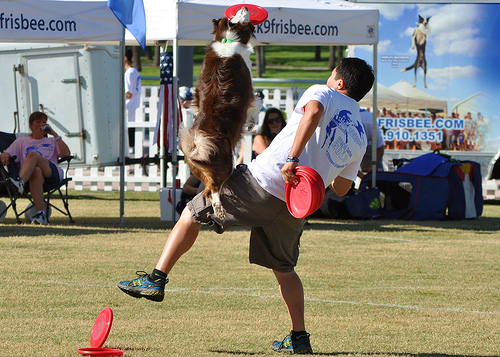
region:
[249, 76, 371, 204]
the man is wearing a white shirt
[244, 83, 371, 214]
the man is wearing a short sleeve shirt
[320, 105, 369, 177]
the shirt has a graphic print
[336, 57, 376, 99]
the man has short hair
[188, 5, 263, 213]
the dog has caugh a frisbee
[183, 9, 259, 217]
the dog is brown and white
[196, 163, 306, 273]
the man is wearing shorts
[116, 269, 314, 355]
the man is wearing sneakers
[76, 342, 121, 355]
a frisbee is on the ground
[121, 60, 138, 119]
a man is in the background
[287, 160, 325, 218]
man holding a stack of red frisbee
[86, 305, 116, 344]
a red frisbee on top of another frisbee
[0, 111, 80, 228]
a woman sitting on a folding chair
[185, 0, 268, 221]
a dog jumping to catch a frisbee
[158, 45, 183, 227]
an American flag on a pole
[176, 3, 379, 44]
a white banner across two poles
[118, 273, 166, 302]
man wearing blue shoes with yellow lines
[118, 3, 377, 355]
man playing frisbee with a dog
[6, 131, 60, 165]
a woman wearing a pink shirt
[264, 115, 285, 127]
woman wearing dark sunglasses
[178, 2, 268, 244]
dog play frisbee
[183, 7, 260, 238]
brown and white dog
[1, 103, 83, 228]
lady sitting in a chair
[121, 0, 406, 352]
guy playing with the dog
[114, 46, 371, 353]
guy wearing a white and blue shirt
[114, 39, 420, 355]
guy holding red frisbees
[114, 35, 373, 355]
guy wearing brown shorts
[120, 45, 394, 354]
guy wearing blue tennis shoes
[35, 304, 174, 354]
red frisbees on the grass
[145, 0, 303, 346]
brown and white dog jumping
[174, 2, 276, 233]
A dog jumping to catch a frisbee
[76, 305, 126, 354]
Two red frisbees on the ground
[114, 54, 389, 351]
A man in a white shirt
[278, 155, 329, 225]
Several frisbees in the man's hand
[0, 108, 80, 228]
A woman sitting in a chair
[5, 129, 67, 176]
A pink shirt on the woman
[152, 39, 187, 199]
An American flag colored wind sock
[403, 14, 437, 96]
A painting of a dog on the sign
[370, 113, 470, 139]
Blue letters on the sign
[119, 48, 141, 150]
A person in a white shirt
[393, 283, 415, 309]
part of a line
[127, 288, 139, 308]
part pof a shoe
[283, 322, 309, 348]
part of a shoe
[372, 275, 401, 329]
part of al oine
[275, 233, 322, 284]
part of a short